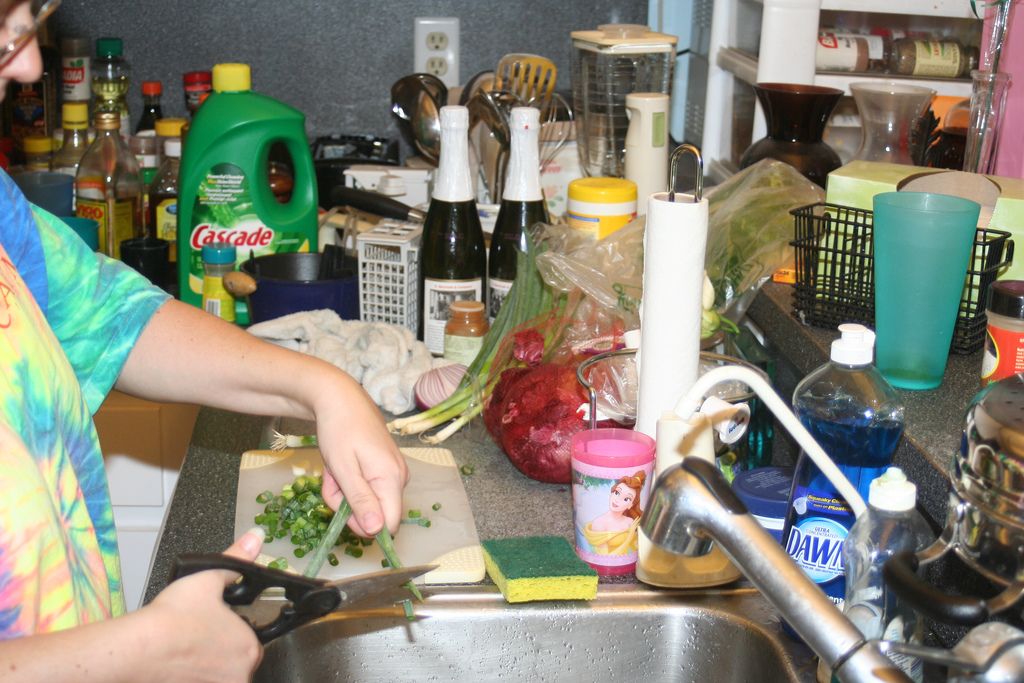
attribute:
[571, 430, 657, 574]
cup — pink